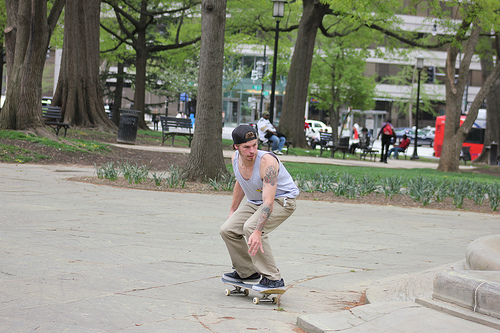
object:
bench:
[159, 115, 194, 147]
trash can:
[115, 108, 143, 145]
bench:
[42, 105, 70, 137]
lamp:
[269, 0, 285, 124]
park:
[1, 0, 499, 332]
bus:
[433, 114, 499, 162]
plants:
[447, 192, 465, 207]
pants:
[218, 196, 297, 281]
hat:
[231, 124, 259, 144]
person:
[375, 119, 397, 163]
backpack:
[382, 124, 394, 136]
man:
[218, 124, 301, 291]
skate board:
[220, 276, 287, 306]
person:
[256, 111, 286, 156]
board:
[220, 272, 287, 304]